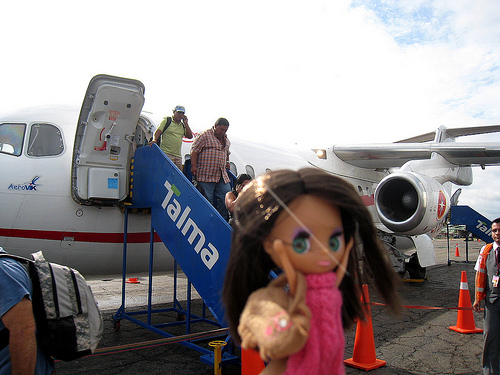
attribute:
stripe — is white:
[458, 280, 472, 292]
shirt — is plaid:
[192, 126, 232, 187]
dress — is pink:
[245, 273, 344, 369]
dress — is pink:
[272, 263, 344, 368]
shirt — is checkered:
[192, 130, 230, 184]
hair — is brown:
[225, 166, 405, 332]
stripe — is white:
[358, 302, 377, 320]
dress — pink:
[249, 273, 350, 373]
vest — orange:
[468, 243, 498, 306]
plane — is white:
[0, 79, 493, 342]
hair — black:
[218, 168, 401, 341]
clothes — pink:
[272, 268, 348, 373]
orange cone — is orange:
[437, 259, 487, 342]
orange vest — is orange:
[470, 223, 499, 309]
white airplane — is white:
[4, 101, 495, 269]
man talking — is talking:
[162, 100, 194, 163]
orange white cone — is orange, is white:
[437, 270, 484, 344]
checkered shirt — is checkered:
[193, 129, 235, 182]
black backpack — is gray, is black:
[19, 240, 122, 370]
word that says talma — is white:
[132, 150, 249, 313]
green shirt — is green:
[153, 112, 193, 162]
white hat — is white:
[169, 105, 188, 122]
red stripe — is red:
[0, 221, 163, 264]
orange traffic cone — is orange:
[350, 280, 389, 367]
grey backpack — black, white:
[19, 237, 115, 370]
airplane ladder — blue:
[117, 142, 283, 363]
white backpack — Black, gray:
[23, 242, 134, 370]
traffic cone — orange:
[228, 331, 266, 370]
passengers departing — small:
[149, 95, 252, 221]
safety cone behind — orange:
[453, 236, 470, 261]